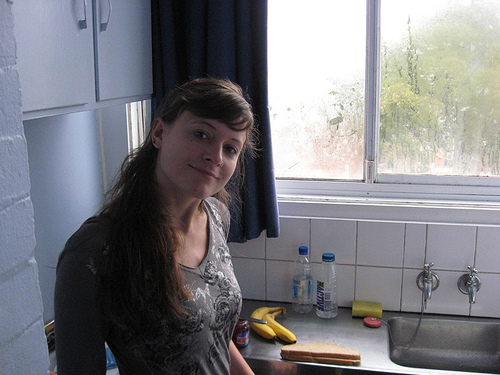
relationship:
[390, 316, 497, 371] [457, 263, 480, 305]
sink has faucet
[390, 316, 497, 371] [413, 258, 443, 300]
sink has faucet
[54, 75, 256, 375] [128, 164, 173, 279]
woman has hair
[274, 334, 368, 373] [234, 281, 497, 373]
sandwich on counter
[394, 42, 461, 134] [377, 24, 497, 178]
streaks on window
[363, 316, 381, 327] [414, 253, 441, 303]
red stopper chained to faucet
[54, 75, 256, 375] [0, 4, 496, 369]
woman in kitchen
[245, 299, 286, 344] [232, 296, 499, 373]
banana on counter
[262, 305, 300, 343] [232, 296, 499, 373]
banana on counter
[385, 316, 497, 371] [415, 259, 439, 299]
sink has faucet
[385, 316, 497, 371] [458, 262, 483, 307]
sink has faucet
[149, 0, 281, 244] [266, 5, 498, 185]
curtain hanging from window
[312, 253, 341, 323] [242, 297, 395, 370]
bottle on counter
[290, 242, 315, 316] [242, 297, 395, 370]
bottle on counter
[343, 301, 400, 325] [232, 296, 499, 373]
sponge on counter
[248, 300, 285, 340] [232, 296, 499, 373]
banana on counter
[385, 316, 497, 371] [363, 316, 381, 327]
sink has red stopper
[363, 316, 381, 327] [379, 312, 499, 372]
red stopper on top of sink